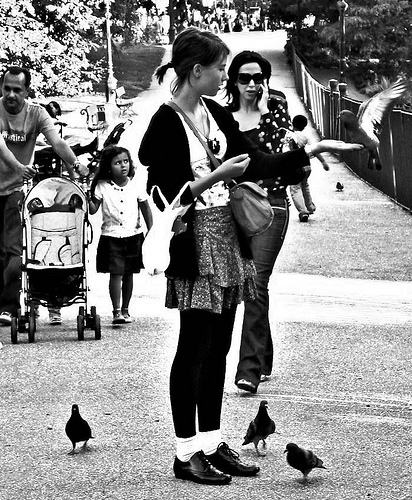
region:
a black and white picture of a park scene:
[0, 0, 410, 497]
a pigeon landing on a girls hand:
[336, 78, 404, 171]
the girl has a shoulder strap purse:
[167, 98, 274, 236]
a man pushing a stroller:
[10, 176, 101, 340]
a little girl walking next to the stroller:
[84, 146, 154, 323]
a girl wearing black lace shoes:
[172, 451, 232, 485]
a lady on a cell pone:
[228, 50, 309, 390]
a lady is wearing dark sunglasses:
[234, 72, 266, 86]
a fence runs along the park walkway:
[283, 17, 340, 117]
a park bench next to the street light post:
[110, 86, 138, 118]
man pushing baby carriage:
[0, 66, 101, 343]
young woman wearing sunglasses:
[224, 50, 310, 393]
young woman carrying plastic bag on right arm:
[140, 28, 260, 488]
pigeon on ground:
[281, 441, 326, 482]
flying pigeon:
[334, 76, 406, 166]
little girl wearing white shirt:
[83, 145, 155, 324]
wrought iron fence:
[289, 48, 411, 215]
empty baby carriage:
[7, 163, 102, 343]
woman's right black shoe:
[171, 448, 231, 485]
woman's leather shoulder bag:
[164, 99, 274, 231]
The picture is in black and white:
[6, 23, 401, 281]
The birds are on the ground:
[183, 395, 341, 499]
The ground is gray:
[18, 347, 126, 404]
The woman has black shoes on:
[149, 441, 280, 498]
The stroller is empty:
[0, 165, 127, 371]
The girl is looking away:
[83, 140, 170, 209]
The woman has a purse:
[178, 158, 304, 249]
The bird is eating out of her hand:
[308, 86, 407, 184]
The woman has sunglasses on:
[219, 53, 275, 94]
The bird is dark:
[43, 395, 123, 460]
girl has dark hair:
[136, 14, 224, 91]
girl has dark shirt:
[142, 90, 262, 230]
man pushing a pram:
[11, 79, 109, 345]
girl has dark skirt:
[101, 235, 147, 272]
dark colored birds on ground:
[198, 375, 355, 495]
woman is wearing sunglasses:
[233, 49, 291, 113]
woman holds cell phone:
[250, 65, 264, 126]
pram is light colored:
[23, 147, 110, 310]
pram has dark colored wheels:
[1, 303, 103, 347]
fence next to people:
[301, 52, 410, 205]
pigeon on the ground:
[254, 423, 367, 477]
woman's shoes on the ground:
[146, 443, 254, 498]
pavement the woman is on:
[324, 333, 381, 436]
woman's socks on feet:
[166, 416, 230, 473]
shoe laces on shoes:
[216, 440, 243, 464]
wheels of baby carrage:
[67, 300, 107, 360]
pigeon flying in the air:
[332, 79, 405, 162]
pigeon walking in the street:
[238, 399, 282, 461]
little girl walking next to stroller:
[57, 128, 142, 345]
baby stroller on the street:
[11, 174, 93, 349]